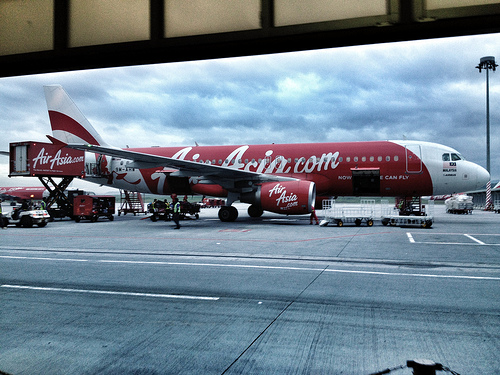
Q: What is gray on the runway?
A: Pavement.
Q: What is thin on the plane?
A: Wing.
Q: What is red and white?
A: Airplane.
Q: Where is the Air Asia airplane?
A: On tarmac.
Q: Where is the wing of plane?
A: On side.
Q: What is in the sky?
A: Clouds.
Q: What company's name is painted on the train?
A: Air Asia.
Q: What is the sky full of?
A: Clouds.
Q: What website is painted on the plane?
A: Airasia.com.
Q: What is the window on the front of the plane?
A: Windshield.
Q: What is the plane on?
A: Ground.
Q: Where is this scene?
A: At the airport.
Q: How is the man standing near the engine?
A: Leaning in.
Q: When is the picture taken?
A: Daytime.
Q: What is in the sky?
A: Clouds.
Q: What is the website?
A: Airasia.com.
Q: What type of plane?
A: An Airbus A320 aircraft.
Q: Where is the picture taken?
A: The airport.